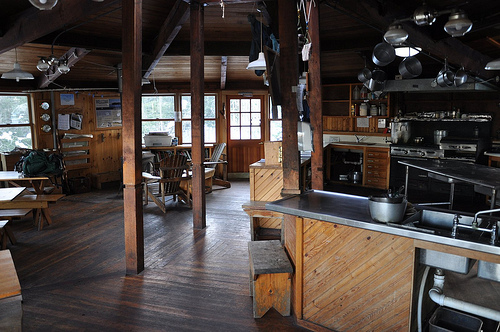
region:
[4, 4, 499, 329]
inside of a rounded wood cabin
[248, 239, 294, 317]
short wooden bench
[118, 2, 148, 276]
wooden beam from the floor to ceiling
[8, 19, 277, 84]
lights hanging from the ceiling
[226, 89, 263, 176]
wide door with a window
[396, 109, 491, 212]
large steel stove area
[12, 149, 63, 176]
dark green back pack sitting on the table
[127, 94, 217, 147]
pair of large windows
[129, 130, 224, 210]
table and chairs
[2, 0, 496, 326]
what a beatuful kicture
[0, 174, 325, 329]
dark brown wood floor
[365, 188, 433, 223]
there are a silver pots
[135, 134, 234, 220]
a table sets next to window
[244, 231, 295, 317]
there are a bench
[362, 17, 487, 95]
there are more silver pots hanging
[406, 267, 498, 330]
there are whire pipes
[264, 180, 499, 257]
thre are silver county top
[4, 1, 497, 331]
this is a resturant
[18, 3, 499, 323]
a restaurant is built of wood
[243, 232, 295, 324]
a wooden bench is near the counter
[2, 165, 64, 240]
picnic tables are in the dining room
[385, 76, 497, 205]
a commercial stove is in the kitchen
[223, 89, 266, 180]
the door of the restaurant has windows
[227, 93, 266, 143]
the door window has mullions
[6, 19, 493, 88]
light fixtures are hanging from the ceilings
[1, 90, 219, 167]
sash windows are on the front of the restaurant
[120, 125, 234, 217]
chairs are in the waiting area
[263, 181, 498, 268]
a stainless steel counter top is in the kitchen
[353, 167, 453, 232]
a silver pot on counter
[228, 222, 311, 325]
a wooden bench agaist counter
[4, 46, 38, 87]
a hanging lamp shade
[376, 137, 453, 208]
a black and silver oven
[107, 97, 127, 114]
a picture on the wall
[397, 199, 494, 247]
a stainless steel sink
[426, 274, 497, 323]
a white plumbing pipe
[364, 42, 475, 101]
pots hanging from ceiling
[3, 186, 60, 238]
a wooden picnic bench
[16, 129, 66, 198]
a green bag on the table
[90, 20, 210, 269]
two wooden posts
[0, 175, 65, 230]
picnic tables in the corner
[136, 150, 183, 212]
wooden chair in middle of floor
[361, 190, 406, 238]
pots on the corner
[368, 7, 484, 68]
pots and pans hanging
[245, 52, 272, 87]
light hanging from the ceiling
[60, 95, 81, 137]
papers on the wall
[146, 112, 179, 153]
basket on the table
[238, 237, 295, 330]
bench made of wood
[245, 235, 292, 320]
small wooden bench with gray top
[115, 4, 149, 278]
tall brown wooden beam reaching the ceiling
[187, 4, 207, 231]
tall brown wooden beam reaching the ceiling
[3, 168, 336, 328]
Dark brown hardwood flooring.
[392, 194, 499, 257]
A silver sink area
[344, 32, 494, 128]
Silver pots and pans hanging up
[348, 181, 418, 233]
Stacked pots on a countertop.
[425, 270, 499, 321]
A white plumbing tube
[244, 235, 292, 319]
A wooden bench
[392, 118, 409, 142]
A large silver pot on the stovetop.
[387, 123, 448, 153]
A stovetop.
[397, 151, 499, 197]
A silver rectangular table.